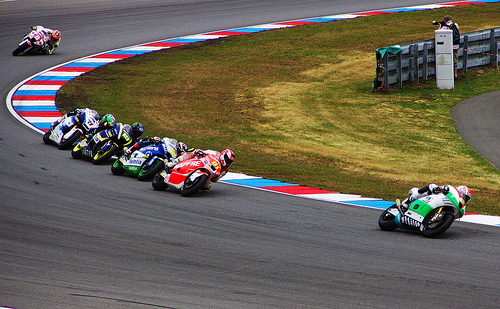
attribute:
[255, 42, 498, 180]
grass — curved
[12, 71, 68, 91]
panel — red